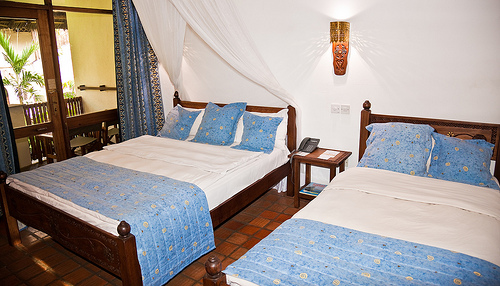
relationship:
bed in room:
[0, 91, 299, 284] [0, 2, 498, 285]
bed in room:
[204, 99, 498, 283] [0, 2, 498, 285]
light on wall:
[329, 20, 349, 75] [157, 5, 497, 191]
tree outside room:
[2, 33, 44, 103] [0, 2, 498, 285]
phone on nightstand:
[288, 135, 320, 166] [288, 142, 353, 208]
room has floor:
[0, 2, 498, 285] [1, 188, 308, 285]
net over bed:
[130, 1, 301, 193] [0, 91, 299, 284]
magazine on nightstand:
[301, 182, 327, 195] [288, 142, 353, 208]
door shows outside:
[1, 8, 68, 170] [2, 2, 121, 172]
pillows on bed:
[358, 119, 500, 191] [204, 99, 498, 283]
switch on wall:
[330, 105, 351, 115] [157, 5, 497, 191]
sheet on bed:
[4, 134, 290, 234] [0, 91, 299, 284]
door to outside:
[1, 8, 68, 170] [2, 2, 121, 172]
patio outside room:
[11, 97, 118, 169] [0, 2, 498, 285]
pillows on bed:
[154, 103, 285, 154] [0, 91, 299, 284]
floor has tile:
[1, 188, 308, 285] [0, 187, 309, 285]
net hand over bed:
[130, 1, 301, 193] [0, 91, 299, 284]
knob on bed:
[117, 220, 132, 235] [0, 91, 299, 284]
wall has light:
[157, 5, 497, 191] [329, 20, 349, 75]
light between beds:
[329, 20, 349, 75] [0, 90, 495, 285]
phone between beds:
[288, 135, 320, 166] [0, 90, 495, 285]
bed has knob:
[0, 91, 299, 284] [117, 220, 132, 235]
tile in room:
[0, 187, 309, 285] [0, 2, 498, 285]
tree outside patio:
[2, 33, 44, 103] [11, 97, 118, 169]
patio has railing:
[11, 97, 118, 169] [24, 94, 84, 163]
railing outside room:
[24, 94, 84, 163] [0, 2, 498, 285]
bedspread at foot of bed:
[8, 156, 216, 284] [0, 91, 299, 284]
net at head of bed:
[130, 1, 301, 193] [0, 91, 299, 284]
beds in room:
[0, 90, 495, 285] [0, 2, 498, 285]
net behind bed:
[130, 1, 301, 193] [0, 91, 299, 284]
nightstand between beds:
[288, 142, 353, 208] [0, 90, 495, 285]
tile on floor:
[0, 187, 309, 285] [1, 188, 308, 285]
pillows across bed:
[358, 119, 500, 191] [204, 99, 498, 283]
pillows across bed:
[154, 103, 285, 154] [0, 91, 299, 284]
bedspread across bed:
[8, 156, 216, 284] [0, 91, 299, 284]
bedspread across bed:
[218, 215, 498, 284] [204, 99, 498, 283]